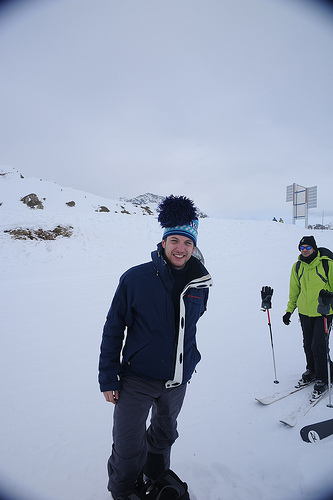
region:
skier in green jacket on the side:
[246, 230, 331, 432]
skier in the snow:
[89, 188, 223, 499]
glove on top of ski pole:
[254, 276, 291, 388]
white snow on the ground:
[9, 261, 96, 484]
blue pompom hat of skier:
[147, 187, 206, 240]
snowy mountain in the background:
[118, 185, 165, 226]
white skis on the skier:
[249, 391, 316, 432]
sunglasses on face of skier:
[299, 242, 315, 252]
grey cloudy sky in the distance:
[9, 15, 330, 154]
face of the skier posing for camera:
[164, 232, 193, 262]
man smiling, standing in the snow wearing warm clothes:
[94, 197, 240, 498]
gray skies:
[3, 8, 328, 191]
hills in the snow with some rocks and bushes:
[5, 138, 161, 297]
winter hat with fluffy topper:
[152, 195, 210, 244]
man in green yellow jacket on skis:
[255, 224, 326, 442]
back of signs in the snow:
[279, 177, 327, 227]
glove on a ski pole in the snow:
[258, 280, 290, 389]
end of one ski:
[291, 420, 330, 459]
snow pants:
[102, 371, 195, 494]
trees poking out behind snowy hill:
[268, 209, 289, 226]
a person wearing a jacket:
[95, 195, 216, 497]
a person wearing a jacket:
[275, 223, 332, 405]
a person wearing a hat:
[93, 184, 210, 493]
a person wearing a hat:
[275, 223, 330, 399]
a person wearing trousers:
[93, 182, 213, 497]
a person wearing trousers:
[279, 219, 332, 402]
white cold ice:
[0, 163, 331, 498]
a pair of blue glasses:
[298, 243, 312, 251]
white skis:
[251, 378, 329, 429]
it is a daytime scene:
[0, 0, 330, 497]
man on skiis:
[103, 185, 219, 488]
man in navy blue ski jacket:
[103, 221, 234, 393]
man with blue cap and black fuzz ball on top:
[129, 189, 207, 268]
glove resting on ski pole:
[243, 281, 291, 347]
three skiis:
[260, 361, 325, 459]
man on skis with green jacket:
[272, 219, 323, 410]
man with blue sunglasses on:
[288, 233, 323, 269]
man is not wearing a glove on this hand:
[85, 373, 126, 408]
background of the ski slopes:
[13, 154, 147, 244]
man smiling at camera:
[145, 226, 202, 277]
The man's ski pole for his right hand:
[260, 280, 288, 391]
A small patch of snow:
[6, 270, 77, 348]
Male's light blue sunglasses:
[298, 245, 312, 251]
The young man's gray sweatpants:
[113, 376, 184, 494]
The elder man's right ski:
[255, 365, 303, 404]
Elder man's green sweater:
[289, 258, 330, 323]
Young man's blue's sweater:
[104, 274, 209, 381]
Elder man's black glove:
[259, 284, 274, 308]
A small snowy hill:
[6, 168, 142, 223]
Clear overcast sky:
[86, 46, 243, 117]